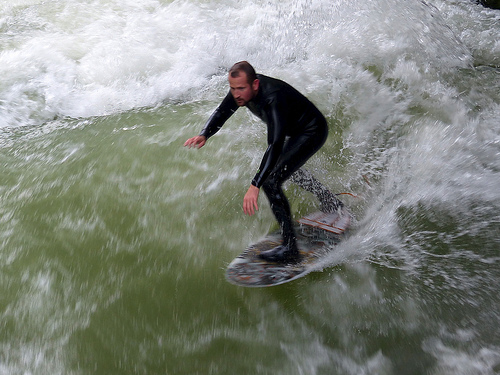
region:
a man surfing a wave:
[14, 9, 477, 358]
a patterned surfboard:
[202, 188, 369, 298]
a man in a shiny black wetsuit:
[183, 55, 320, 270]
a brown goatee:
[226, 92, 256, 110]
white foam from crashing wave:
[11, 8, 448, 140]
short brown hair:
[227, 56, 263, 86]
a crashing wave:
[301, 17, 484, 279]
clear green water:
[13, 115, 225, 343]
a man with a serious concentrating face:
[226, 72, 256, 108]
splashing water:
[306, 99, 463, 284]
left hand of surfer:
[223, 180, 280, 203]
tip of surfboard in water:
[187, 264, 351, 281]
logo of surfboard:
[290, 184, 355, 238]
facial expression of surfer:
[220, 70, 262, 116]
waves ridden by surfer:
[31, 51, 138, 176]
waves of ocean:
[331, 42, 431, 147]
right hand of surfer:
[170, 106, 217, 149]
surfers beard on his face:
[226, 89, 248, 107]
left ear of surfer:
[247, 76, 273, 87]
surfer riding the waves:
[202, 52, 364, 312]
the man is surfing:
[181, 42, 409, 332]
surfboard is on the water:
[149, 174, 387, 320]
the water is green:
[93, 157, 231, 361]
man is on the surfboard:
[201, 62, 350, 291]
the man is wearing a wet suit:
[179, 21, 386, 323]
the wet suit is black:
[188, 80, 340, 312]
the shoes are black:
[233, 185, 350, 279]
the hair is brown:
[214, 61, 271, 97]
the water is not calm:
[28, 28, 380, 344]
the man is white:
[183, 45, 334, 247]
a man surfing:
[175, 63, 356, 313]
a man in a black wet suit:
[202, 58, 352, 295]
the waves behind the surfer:
[337, 41, 476, 271]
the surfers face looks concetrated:
[219, 58, 273, 115]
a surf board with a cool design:
[182, 198, 377, 293]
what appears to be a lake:
[54, 87, 196, 329]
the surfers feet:
[256, 246, 316, 266]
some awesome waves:
[361, 12, 459, 250]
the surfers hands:
[191, 141, 266, 226]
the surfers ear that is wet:
[249, 80, 262, 92]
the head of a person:
[223, 57, 258, 108]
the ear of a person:
[248, 78, 262, 93]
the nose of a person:
[232, 92, 239, 99]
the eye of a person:
[237, 83, 247, 92]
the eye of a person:
[227, 84, 235, 91]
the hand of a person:
[240, 92, 285, 219]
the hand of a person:
[179, 96, 240, 153]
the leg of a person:
[261, 165, 303, 278]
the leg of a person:
[289, 168, 351, 215]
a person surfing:
[168, 37, 402, 306]